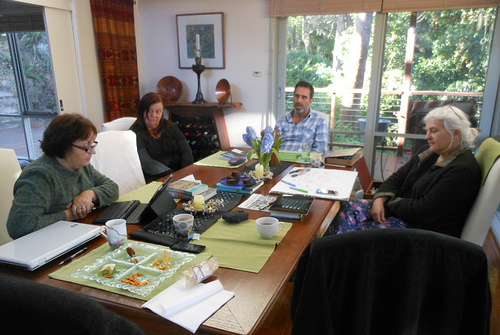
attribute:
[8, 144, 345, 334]
table — long, wooden, rectangular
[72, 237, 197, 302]
bowl — snacks, divided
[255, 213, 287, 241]
cup — white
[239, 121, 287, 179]
plant — blue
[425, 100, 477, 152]
hair — grey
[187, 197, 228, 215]
candle holder — tall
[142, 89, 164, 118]
hair — red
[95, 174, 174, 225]
laptop — black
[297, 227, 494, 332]
jacket — draped, black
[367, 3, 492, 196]
door — sliding